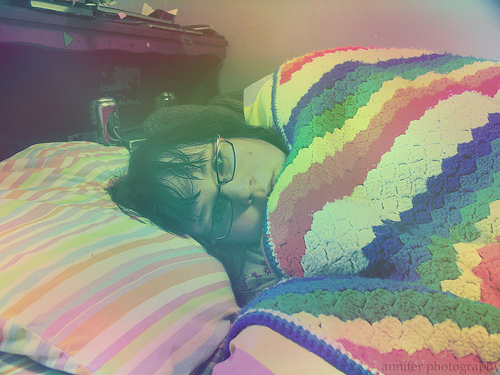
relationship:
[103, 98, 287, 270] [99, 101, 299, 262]
hair on head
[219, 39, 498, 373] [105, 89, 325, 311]
blanket on girl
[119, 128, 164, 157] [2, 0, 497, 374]
clock next to bed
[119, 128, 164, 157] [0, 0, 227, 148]
clock on table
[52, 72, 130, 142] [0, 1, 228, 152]
can on headboard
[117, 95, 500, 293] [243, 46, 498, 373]
person under blanket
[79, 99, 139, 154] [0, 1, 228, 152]
paper on headboard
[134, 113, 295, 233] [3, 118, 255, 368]
head on pillow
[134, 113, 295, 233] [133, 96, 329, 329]
head on girl